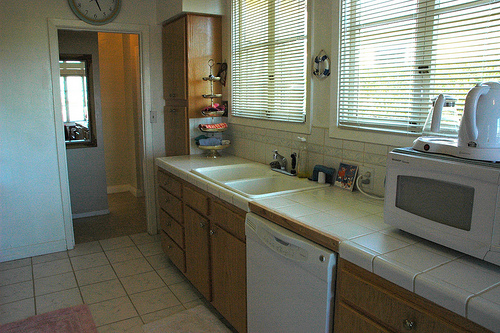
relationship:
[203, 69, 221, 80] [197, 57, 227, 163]
tray on stand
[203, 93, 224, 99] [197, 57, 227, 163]
tray on stand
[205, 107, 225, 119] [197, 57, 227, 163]
tray on stand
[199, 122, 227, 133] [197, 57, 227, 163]
tray on stand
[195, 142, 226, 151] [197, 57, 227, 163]
tray on stand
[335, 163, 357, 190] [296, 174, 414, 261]
picture on cabinet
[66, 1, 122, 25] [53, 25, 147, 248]
clock over door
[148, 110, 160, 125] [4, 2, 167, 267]
light switch on wall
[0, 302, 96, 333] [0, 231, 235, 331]
mat on floor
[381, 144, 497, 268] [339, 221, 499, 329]
microwave on counter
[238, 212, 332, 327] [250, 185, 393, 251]
dishwasher under counter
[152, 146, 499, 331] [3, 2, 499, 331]
counter in kitchen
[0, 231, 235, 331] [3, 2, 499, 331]
floor in kitchen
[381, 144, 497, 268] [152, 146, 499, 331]
microwave sitting on counter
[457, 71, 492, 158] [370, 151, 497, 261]
coffee maker on microwave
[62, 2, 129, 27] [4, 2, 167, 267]
clock on wall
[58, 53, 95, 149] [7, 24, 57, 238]
mirror hanging on wall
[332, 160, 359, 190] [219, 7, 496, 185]
picture leaning on wall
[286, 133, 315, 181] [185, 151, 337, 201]
bottle next to sink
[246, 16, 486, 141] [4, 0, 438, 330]
windows in kitchen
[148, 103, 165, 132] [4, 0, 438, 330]
switch in kitchen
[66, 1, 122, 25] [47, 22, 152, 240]
clock hanging above doorway